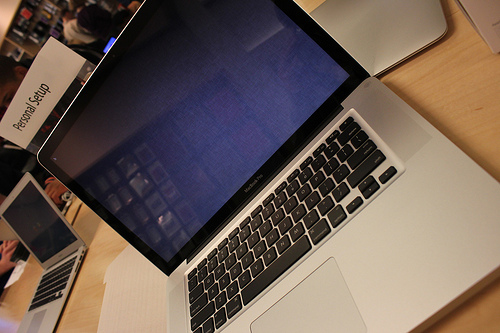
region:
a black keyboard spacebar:
[240, 235, 312, 305]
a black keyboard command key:
[225, 295, 243, 321]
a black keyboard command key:
[307, 218, 331, 245]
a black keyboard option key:
[327, 203, 347, 228]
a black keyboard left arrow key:
[345, 196, 362, 214]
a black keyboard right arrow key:
[379, 165, 396, 182]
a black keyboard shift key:
[346, 148, 386, 186]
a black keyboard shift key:
[189, 300, 214, 330]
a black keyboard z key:
[215, 291, 228, 309]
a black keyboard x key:
[225, 280, 237, 298]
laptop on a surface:
[9, 3, 491, 318]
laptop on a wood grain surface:
[2, 1, 494, 324]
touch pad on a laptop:
[246, 249, 363, 331]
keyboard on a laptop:
[183, 103, 395, 330]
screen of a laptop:
[35, 0, 368, 277]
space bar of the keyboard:
[238, 233, 310, 303]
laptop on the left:
[0, 165, 86, 328]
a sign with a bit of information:
[0, 26, 85, 158]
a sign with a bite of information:
[2, 30, 83, 155]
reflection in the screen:
[82, 58, 302, 261]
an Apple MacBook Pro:
[36, 0, 498, 332]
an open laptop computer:
[36, 0, 499, 332]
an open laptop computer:
[0, 173, 87, 331]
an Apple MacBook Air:
[0, 172, 88, 330]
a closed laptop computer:
[306, 0, 450, 77]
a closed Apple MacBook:
[308, 0, 452, 78]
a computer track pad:
[250, 258, 364, 330]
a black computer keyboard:
[189, 111, 396, 331]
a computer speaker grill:
[354, 90, 433, 160]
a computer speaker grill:
[166, 271, 186, 331]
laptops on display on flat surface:
[6, 12, 491, 322]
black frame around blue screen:
[42, 1, 354, 271]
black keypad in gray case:
[157, 80, 493, 330]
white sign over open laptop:
[2, 21, 84, 161]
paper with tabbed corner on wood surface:
[81, 245, 176, 325]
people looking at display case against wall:
[0, 0, 130, 110]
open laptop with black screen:
[0, 175, 85, 330]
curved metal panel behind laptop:
[305, 0, 450, 85]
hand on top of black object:
[0, 225, 30, 290]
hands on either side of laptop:
[1, 166, 66, 276]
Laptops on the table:
[3, 28, 498, 330]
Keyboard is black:
[163, 188, 383, 331]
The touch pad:
[241, 291, 371, 331]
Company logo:
[228, 171, 273, 198]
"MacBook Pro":
[233, 168, 268, 195]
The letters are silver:
[239, 171, 272, 192]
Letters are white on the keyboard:
[173, 228, 326, 323]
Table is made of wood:
[71, 282, 97, 328]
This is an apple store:
[1, 3, 490, 329]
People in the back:
[47, 2, 127, 56]